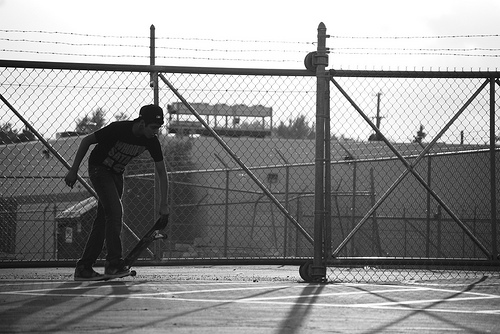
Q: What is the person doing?
A: Skateboarding.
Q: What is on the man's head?
A: A hat.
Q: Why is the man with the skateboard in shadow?
A: The sun is not overhead, but probably low on the horizon.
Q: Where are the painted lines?
A: On the black top of the yard..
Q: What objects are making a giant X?
A: Metal bars, criss-crossing a chain link fence.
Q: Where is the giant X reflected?
A: In shadow, on the ground.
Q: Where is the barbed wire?
A: Overtopping the metal gates, supporting the chain links.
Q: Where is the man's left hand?
A: Supporting the tip of the skate board.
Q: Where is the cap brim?
A: Above the neck of the skateboarder.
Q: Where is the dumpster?
A: Near the left side of the building that is beyond the series of fences.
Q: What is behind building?
A: Trees.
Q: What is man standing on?
A: Skateboard.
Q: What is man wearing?
A: Shirt and jeans.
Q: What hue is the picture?
A: Black and white.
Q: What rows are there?
A: Three.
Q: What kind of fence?
A: Sliding.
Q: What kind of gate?
A: Chain link.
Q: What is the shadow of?
A: Fence.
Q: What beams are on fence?
A: Support.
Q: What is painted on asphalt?
A: Lines.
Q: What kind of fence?
A: Chain link.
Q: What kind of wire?
A: Barbed.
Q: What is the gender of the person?
A: Male.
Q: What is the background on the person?
A: Wire-mesh fence.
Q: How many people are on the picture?
A: One.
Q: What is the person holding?
A: Skate board.